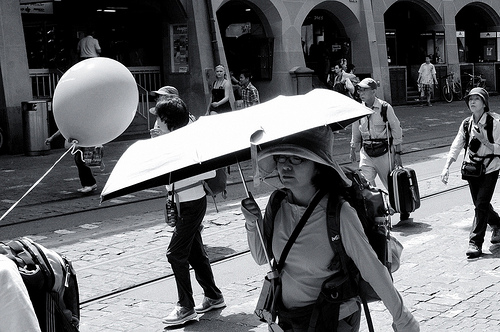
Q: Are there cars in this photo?
A: No, there are no cars.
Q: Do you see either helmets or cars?
A: No, there are no cars or helmets.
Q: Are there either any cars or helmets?
A: No, there are no cars or helmets.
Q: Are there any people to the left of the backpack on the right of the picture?
A: Yes, there is a person to the left of the backpack.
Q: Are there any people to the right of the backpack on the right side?
A: No, the person is to the left of the backpack.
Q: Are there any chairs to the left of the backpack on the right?
A: No, there is a person to the left of the backpack.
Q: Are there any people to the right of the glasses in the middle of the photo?
A: Yes, there is a person to the right of the glasses.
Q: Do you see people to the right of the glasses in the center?
A: Yes, there is a person to the right of the glasses.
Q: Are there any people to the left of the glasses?
A: No, the person is to the right of the glasses.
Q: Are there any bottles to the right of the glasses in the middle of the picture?
A: No, there is a person to the right of the glasses.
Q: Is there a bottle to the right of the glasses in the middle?
A: No, there is a person to the right of the glasses.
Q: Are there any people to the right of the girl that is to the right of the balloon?
A: Yes, there is a person to the right of the girl.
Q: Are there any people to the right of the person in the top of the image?
A: Yes, there is a person to the right of the girl.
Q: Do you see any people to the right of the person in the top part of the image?
A: Yes, there is a person to the right of the girl.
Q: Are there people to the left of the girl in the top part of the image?
A: No, the person is to the right of the girl.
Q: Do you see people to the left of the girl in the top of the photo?
A: No, the person is to the right of the girl.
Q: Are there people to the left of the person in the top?
A: No, the person is to the right of the girl.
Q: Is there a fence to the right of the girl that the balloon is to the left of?
A: No, there is a person to the right of the girl.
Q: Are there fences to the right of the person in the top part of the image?
A: No, there is a person to the right of the girl.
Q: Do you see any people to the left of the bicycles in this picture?
A: Yes, there is a person to the left of the bicycles.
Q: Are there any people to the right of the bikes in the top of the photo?
A: No, the person is to the left of the bikes.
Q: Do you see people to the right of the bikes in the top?
A: No, the person is to the left of the bikes.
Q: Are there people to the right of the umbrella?
A: Yes, there is a person to the right of the umbrella.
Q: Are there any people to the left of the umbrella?
A: No, the person is to the right of the umbrella.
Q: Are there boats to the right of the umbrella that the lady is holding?
A: No, there is a person to the right of the umbrella.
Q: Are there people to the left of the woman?
A: Yes, there is a person to the left of the woman.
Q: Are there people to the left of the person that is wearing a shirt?
A: Yes, there is a person to the left of the woman.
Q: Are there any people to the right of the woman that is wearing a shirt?
A: No, the person is to the left of the woman.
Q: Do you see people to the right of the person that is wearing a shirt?
A: No, the person is to the left of the woman.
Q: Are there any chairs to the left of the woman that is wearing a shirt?
A: No, there is a person to the left of the woman.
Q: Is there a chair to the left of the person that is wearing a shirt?
A: No, there is a person to the left of the woman.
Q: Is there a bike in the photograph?
A: Yes, there are bikes.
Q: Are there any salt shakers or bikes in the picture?
A: Yes, there are bikes.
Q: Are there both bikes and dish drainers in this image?
A: No, there are bikes but no dish drainers.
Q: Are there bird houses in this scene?
A: No, there are no bird houses.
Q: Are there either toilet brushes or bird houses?
A: No, there are no bird houses or toilet brushes.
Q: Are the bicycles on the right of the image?
A: Yes, the bicycles are on the right of the image.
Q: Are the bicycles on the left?
A: No, the bicycles are on the right of the image.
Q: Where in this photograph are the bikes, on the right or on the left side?
A: The bikes are on the right of the image.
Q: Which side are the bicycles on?
A: The bicycles are on the right of the image.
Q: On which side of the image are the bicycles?
A: The bicycles are on the right of the image.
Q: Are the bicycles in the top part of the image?
A: Yes, the bicycles are in the top of the image.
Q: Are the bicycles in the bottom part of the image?
A: No, the bicycles are in the top of the image.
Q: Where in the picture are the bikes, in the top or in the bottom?
A: The bikes are in the top of the image.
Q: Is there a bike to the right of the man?
A: Yes, there are bikes to the right of the man.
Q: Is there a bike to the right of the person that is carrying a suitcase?
A: Yes, there are bikes to the right of the man.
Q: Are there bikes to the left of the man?
A: No, the bikes are to the right of the man.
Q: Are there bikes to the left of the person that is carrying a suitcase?
A: No, the bikes are to the right of the man.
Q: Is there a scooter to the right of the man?
A: No, there are bikes to the right of the man.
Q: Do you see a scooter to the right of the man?
A: No, there are bikes to the right of the man.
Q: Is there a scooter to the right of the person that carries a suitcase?
A: No, there are bikes to the right of the man.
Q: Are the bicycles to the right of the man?
A: Yes, the bicycles are to the right of the man.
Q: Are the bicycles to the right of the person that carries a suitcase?
A: Yes, the bicycles are to the right of the man.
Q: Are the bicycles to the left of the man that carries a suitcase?
A: No, the bicycles are to the right of the man.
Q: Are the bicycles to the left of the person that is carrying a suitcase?
A: No, the bicycles are to the right of the man.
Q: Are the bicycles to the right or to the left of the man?
A: The bicycles are to the right of the man.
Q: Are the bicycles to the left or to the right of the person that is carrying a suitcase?
A: The bicycles are to the right of the man.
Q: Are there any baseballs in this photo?
A: No, there are no baseballs.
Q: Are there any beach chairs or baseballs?
A: No, there are no baseballs or beach chairs.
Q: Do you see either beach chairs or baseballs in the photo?
A: No, there are no baseballs or beach chairs.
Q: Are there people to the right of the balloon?
A: Yes, there are people to the right of the balloon.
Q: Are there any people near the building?
A: Yes, there are people near the building.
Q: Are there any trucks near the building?
A: No, there are people near the building.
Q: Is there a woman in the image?
A: Yes, there is a woman.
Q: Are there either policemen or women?
A: Yes, there is a woman.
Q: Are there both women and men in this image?
A: Yes, there are both a woman and a man.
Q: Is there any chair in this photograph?
A: No, there are no chairs.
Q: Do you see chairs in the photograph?
A: No, there are no chairs.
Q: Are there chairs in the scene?
A: No, there are no chairs.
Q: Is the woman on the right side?
A: Yes, the woman is on the right of the image.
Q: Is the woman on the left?
A: No, the woman is on the right of the image.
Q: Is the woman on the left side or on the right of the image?
A: The woman is on the right of the image.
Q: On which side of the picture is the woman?
A: The woman is on the right of the image.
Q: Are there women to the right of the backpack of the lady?
A: Yes, there is a woman to the right of the backpack.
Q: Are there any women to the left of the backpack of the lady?
A: No, the woman is to the right of the backpack.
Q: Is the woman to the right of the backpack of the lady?
A: Yes, the woman is to the right of the backpack.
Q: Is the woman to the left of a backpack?
A: No, the woman is to the right of a backpack.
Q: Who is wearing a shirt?
A: The woman is wearing a shirt.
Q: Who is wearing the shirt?
A: The woman is wearing a shirt.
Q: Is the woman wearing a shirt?
A: Yes, the woman is wearing a shirt.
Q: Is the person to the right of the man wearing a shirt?
A: Yes, the woman is wearing a shirt.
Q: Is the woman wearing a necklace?
A: No, the woman is wearing a shirt.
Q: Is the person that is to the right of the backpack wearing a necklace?
A: No, the woman is wearing a shirt.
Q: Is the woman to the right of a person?
A: Yes, the woman is to the right of a person.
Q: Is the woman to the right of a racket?
A: No, the woman is to the right of a person.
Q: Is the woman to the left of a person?
A: No, the woman is to the right of a person.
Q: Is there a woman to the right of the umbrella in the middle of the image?
A: Yes, there is a woman to the right of the umbrella.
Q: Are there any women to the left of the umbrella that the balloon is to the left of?
A: No, the woman is to the right of the umbrella.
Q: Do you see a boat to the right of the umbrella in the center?
A: No, there is a woman to the right of the umbrella.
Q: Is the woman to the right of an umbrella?
A: Yes, the woman is to the right of an umbrella.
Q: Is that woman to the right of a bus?
A: No, the woman is to the right of an umbrella.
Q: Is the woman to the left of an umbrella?
A: No, the woman is to the right of an umbrella.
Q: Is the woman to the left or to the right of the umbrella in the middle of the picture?
A: The woman is to the right of the umbrella.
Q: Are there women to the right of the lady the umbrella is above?
A: Yes, there is a woman to the right of the lady.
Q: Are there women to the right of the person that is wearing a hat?
A: Yes, there is a woman to the right of the lady.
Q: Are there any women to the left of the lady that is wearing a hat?
A: No, the woman is to the right of the lady.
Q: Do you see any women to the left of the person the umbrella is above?
A: No, the woman is to the right of the lady.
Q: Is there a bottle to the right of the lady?
A: No, there is a woman to the right of the lady.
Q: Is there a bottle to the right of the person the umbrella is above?
A: No, there is a woman to the right of the lady.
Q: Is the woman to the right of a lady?
A: Yes, the woman is to the right of a lady.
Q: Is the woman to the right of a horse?
A: No, the woman is to the right of a lady.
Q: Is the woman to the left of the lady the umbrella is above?
A: No, the woman is to the right of the lady.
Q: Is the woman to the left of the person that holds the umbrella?
A: No, the woman is to the right of the lady.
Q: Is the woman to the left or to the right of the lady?
A: The woman is to the right of the lady.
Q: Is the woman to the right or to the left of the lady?
A: The woman is to the right of the lady.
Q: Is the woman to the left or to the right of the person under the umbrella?
A: The woman is to the right of the lady.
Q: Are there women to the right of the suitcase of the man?
A: Yes, there is a woman to the right of the suitcase.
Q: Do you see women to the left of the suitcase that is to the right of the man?
A: No, the woman is to the right of the suitcase.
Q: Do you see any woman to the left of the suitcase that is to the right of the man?
A: No, the woman is to the right of the suitcase.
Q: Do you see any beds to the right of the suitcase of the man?
A: No, there is a woman to the right of the suitcase.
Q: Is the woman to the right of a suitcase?
A: Yes, the woman is to the right of a suitcase.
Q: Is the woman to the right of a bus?
A: No, the woman is to the right of a suitcase.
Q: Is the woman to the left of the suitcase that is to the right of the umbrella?
A: No, the woman is to the right of the suitcase.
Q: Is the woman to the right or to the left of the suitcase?
A: The woman is to the right of the suitcase.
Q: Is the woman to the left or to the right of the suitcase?
A: The woman is to the right of the suitcase.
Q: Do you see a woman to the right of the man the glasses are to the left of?
A: Yes, there is a woman to the right of the man.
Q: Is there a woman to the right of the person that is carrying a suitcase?
A: Yes, there is a woman to the right of the man.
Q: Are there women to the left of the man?
A: No, the woman is to the right of the man.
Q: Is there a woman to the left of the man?
A: No, the woman is to the right of the man.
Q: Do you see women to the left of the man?
A: No, the woman is to the right of the man.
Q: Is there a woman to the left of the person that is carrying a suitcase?
A: No, the woman is to the right of the man.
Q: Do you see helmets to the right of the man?
A: No, there is a woman to the right of the man.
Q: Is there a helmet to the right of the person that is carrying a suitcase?
A: No, there is a woman to the right of the man.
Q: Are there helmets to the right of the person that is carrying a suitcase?
A: No, there is a woman to the right of the man.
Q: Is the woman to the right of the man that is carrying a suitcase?
A: Yes, the woman is to the right of the man.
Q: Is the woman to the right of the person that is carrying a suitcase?
A: Yes, the woman is to the right of the man.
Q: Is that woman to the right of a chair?
A: No, the woman is to the right of the man.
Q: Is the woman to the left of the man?
A: No, the woman is to the right of the man.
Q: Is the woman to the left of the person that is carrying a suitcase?
A: No, the woman is to the right of the man.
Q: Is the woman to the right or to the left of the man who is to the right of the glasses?
A: The woman is to the right of the man.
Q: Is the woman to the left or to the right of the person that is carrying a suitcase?
A: The woman is to the right of the man.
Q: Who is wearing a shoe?
A: The woman is wearing a shoe.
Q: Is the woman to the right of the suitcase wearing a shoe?
A: Yes, the woman is wearing a shoe.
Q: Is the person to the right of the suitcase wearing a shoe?
A: Yes, the woman is wearing a shoe.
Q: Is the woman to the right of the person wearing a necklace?
A: No, the woman is wearing a shoe.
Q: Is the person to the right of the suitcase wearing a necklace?
A: No, the woman is wearing a shoe.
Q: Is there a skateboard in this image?
A: No, there are no skateboards.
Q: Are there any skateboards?
A: No, there are no skateboards.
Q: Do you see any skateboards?
A: No, there are no skateboards.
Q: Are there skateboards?
A: No, there are no skateboards.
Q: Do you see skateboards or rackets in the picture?
A: No, there are no skateboards or rackets.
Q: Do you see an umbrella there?
A: Yes, there is an umbrella.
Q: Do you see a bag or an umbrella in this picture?
A: Yes, there is an umbrella.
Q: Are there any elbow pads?
A: No, there are no elbow pads.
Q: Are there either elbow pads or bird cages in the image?
A: No, there are no elbow pads or bird cages.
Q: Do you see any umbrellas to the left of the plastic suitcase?
A: Yes, there is an umbrella to the left of the suitcase.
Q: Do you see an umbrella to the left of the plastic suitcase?
A: Yes, there is an umbrella to the left of the suitcase.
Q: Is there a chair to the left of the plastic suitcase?
A: No, there is an umbrella to the left of the suitcase.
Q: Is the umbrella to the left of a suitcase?
A: Yes, the umbrella is to the left of a suitcase.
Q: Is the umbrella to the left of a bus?
A: No, the umbrella is to the left of a suitcase.